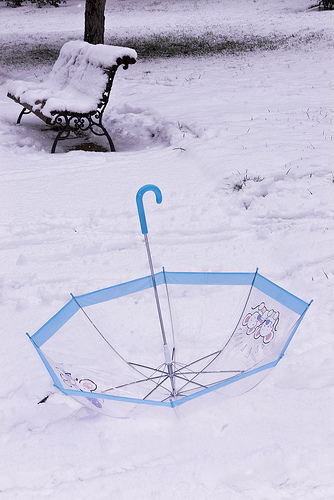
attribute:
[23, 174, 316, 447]
umbrella — white, plastic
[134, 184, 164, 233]
handle — big, cane shaped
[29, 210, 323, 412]
umbrella — blue, Plastic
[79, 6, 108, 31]
trunk — tree trunk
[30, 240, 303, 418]
umbrella — large, transparent, Upside down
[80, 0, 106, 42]
tree trunk — white, dark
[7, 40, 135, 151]
bench — metal, iron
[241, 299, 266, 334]
mouse — upside down, cartoon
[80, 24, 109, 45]
trunk — tree